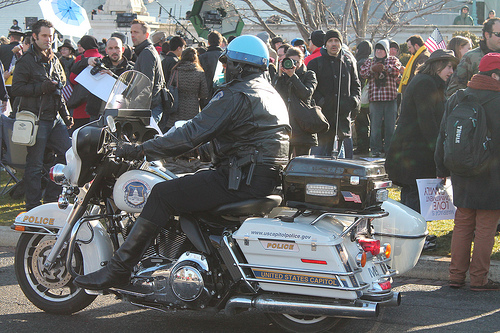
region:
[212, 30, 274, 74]
The cop is wearing a blue helmet.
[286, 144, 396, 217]
Black box on the motorcycle.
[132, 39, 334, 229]
The cop is riding the motorcycle.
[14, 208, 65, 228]
The word police on the front wheel.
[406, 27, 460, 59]
A person holding an American flag.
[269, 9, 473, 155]
People standing around on the grass.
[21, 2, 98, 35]
The umbrella is open.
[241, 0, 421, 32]
The tree is bare.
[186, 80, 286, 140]
The police officer is wearing a leather jacket.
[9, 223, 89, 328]
The tire of the motorcycle.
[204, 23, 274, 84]
Police officer wearing a helmet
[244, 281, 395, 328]
silver exhaust pipe of a motorcycle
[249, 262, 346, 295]
United States Capitol written on motorcycle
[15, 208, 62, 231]
Police written on motorcycle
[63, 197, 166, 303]
black boot of a motorcycle police officer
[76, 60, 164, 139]
wind screen of a police motorcycle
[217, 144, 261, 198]
police officer wearing a pistol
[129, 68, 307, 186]
police officer wearing a black leather jacket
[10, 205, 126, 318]
front fender of a police motorcycle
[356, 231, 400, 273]
rear tail lights of a motorcycle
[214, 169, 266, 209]
he is riding the bike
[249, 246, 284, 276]
the bike is white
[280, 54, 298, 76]
the person is holding a camera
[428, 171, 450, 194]
the personn is holding a sign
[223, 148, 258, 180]
the gun is in the holster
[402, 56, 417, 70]
the scarf is yellow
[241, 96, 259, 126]
the coat is black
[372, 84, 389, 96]
the coat is plaid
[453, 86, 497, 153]
the person is carrying a pack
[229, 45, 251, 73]
he is wearing a helmet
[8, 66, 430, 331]
a police model motorcycle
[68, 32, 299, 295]
a motorcycle police officer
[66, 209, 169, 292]
a black leather boot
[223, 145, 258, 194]
a holstered black pistol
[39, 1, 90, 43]
a blue and white umbrella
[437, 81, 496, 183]
a black backpack with a white logo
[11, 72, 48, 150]
a town and brown shoulder bag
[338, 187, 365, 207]
a united states of america flag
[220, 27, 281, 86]
a white and black motorcycle helmet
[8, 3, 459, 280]
this is at a parade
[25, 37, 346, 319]
there are many people gathered here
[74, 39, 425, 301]
this is a policeman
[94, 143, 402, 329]
this is a motorcyle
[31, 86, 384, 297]
the cop is on a motorcycle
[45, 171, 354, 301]
the motorcycle is white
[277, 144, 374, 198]
this compartment is black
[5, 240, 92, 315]
the tire is made of metal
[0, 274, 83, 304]
the tire is black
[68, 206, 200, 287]
the policeman is wearing boots